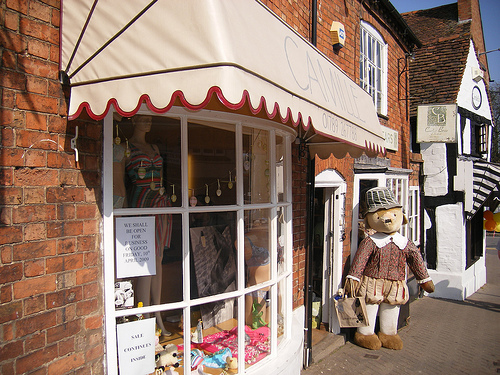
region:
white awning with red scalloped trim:
[58, 0, 435, 150]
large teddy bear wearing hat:
[328, 178, 438, 353]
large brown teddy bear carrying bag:
[328, 182, 440, 352]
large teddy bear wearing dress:
[328, 179, 440, 351]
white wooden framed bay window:
[103, 109, 337, 374]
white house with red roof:
[410, 1, 498, 308]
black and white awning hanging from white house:
[460, 157, 499, 220]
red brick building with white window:
[1, 0, 428, 368]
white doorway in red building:
[312, 166, 345, 353]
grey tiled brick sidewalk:
[306, 247, 498, 371]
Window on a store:
[98, 136, 283, 373]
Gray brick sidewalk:
[417, 301, 498, 358]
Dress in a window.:
[111, 136, 182, 250]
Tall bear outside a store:
[346, 185, 430, 356]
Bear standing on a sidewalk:
[342, 185, 443, 349]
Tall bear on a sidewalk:
[342, 166, 437, 352]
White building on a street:
[411, 81, 496, 323]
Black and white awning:
[482, 148, 498, 229]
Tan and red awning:
[66, 17, 419, 182]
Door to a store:
[302, 170, 418, 372]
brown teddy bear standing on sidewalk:
[331, 174, 440, 356]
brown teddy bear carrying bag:
[334, 185, 440, 351]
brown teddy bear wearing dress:
[343, 180, 438, 349]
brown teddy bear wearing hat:
[334, 180, 433, 356]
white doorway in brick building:
[307, 160, 354, 362]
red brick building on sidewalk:
[12, 2, 424, 367]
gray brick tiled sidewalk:
[312, 280, 499, 370]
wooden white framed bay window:
[93, 117, 310, 366]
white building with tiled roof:
[401, 0, 499, 303]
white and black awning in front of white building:
[462, 156, 499, 233]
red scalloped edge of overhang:
[109, 83, 207, 125]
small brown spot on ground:
[355, 341, 400, 368]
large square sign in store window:
[112, 211, 165, 273]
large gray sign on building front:
[276, 34, 393, 123]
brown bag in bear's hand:
[313, 267, 382, 337]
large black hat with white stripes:
[340, 177, 421, 217]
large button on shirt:
[388, 236, 394, 246]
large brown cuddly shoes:
[353, 322, 464, 357]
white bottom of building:
[423, 261, 498, 301]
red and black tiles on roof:
[410, 31, 468, 103]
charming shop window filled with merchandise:
[55, 38, 322, 360]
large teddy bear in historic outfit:
[325, 176, 435, 352]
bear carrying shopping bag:
[326, 265, 406, 350]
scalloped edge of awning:
[61, 81, 306, 126]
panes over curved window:
[117, 137, 327, 364]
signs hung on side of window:
[111, 190, 161, 370]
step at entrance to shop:
[295, 306, 352, 361]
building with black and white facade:
[425, 45, 495, 295]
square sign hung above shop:
[405, 92, 460, 144]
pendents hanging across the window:
[116, 136, 277, 212]